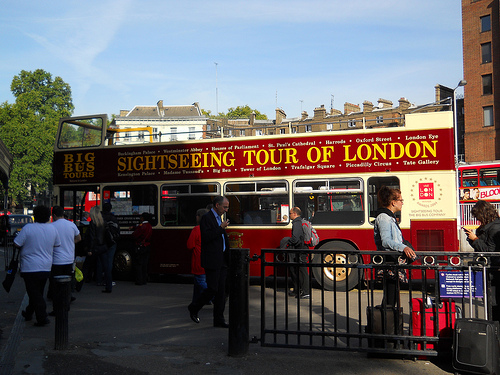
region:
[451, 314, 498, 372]
black suitcase on ground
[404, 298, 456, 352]
red suitcase on ground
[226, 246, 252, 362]
black pole on the ground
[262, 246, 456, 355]
black gate that's outside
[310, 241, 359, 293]
black tire on bus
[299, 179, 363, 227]
window on the bus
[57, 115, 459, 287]
double decker red bus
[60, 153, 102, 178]
yellow print on bus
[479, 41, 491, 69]
window on brown building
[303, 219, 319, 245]
backpack on the man's back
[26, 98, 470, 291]
guided tour bus in London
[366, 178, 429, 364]
woman with long red hair grasping iron baracade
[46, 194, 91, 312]
man with yellow hat hanging from belt loop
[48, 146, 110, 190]
tour bus reads big bus tours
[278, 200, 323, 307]
man wearing black pants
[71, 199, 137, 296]
woman with long blond hair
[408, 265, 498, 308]
blue sign with white writing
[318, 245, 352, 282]
rust on hub cap of tire on bus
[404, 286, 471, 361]
red bag on ground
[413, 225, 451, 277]
vent in side of tour bus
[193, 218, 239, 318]
the suit is black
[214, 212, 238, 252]
the shirt is blue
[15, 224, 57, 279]
the shirt is wite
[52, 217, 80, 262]
the shirt is white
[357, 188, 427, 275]
the woman has glasses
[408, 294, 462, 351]
the bag is red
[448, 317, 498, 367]
the bag is black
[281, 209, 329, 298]
the man has a backpack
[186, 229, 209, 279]
the shirt is red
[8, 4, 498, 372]
the scene is in london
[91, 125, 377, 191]
this is a bus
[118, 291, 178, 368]
this is the road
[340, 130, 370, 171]
it is red in color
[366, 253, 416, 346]
the fence is metallic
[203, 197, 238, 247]
this is a man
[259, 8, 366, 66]
this is the sky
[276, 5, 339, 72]
the sky is blue in color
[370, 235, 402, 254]
this is the hand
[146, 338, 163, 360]
part of a floor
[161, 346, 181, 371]
part of a floor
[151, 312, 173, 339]
part of a floor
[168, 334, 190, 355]
part of a floor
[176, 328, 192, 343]
part of a floor